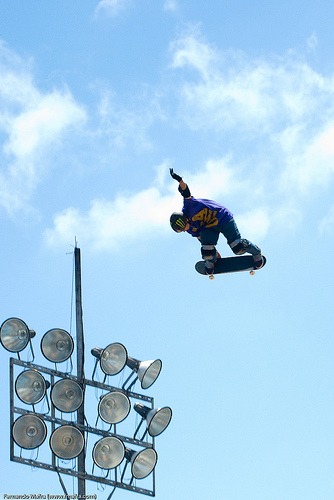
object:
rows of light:
[3, 315, 173, 499]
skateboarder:
[166, 168, 268, 278]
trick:
[191, 252, 267, 279]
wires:
[2, 232, 159, 499]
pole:
[73, 245, 88, 499]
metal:
[9, 354, 159, 498]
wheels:
[206, 269, 256, 278]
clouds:
[2, 2, 334, 284]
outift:
[181, 198, 256, 258]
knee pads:
[198, 243, 250, 260]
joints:
[194, 239, 250, 260]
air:
[2, 2, 332, 500]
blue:
[182, 196, 230, 237]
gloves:
[170, 169, 181, 183]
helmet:
[169, 213, 184, 234]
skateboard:
[193, 254, 266, 279]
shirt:
[182, 196, 229, 233]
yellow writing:
[193, 208, 219, 229]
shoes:
[204, 248, 263, 269]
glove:
[167, 166, 180, 178]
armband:
[178, 186, 192, 199]